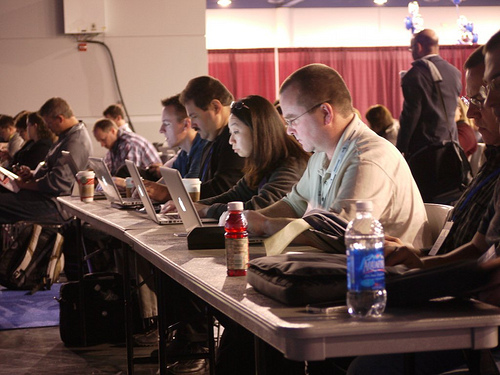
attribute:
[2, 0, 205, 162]
wall — made of stone, white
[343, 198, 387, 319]
bottle — made of plastic, clear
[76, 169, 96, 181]
lid — white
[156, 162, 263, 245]
laptop — grey, open, an apple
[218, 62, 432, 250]
person — sitting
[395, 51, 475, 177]
coat — black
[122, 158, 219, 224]
laptop — silver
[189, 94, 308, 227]
woman — sitting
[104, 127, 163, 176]
shirt — plaid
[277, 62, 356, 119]
hair — balding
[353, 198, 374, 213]
lid — white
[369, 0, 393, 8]
light — turned on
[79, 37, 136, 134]
cable — black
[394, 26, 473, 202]
guy — standing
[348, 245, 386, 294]
label — blue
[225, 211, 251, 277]
liquid — red, fruit drink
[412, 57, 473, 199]
bag — hanging down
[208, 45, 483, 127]
curtain — red